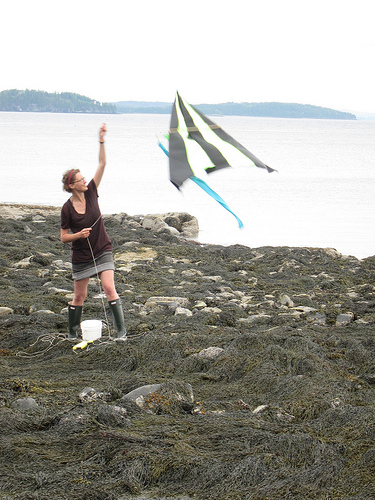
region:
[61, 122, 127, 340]
A woman holding a kite string up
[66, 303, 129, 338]
A pair of black rainboots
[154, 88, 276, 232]
A black, white, and blue kite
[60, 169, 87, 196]
A woman with a pink hairband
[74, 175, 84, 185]
A pair of glasses on her face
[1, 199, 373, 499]
A rocky cliff by the water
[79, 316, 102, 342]
A white bucket on the ground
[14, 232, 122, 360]
White kite string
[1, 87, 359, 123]
Trees and land across the water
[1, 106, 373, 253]
Water between the two areas of land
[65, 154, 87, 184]
girl has brown hair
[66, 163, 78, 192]
girl has pink headband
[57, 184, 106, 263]
girl has brown shirt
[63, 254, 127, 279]
girl has grey skirt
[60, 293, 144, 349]
girl has black boots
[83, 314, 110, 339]
white bucket near girl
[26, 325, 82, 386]
grey rope near bucket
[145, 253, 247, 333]
grey rocks on cliff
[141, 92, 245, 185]
black and white kite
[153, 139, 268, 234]
blue streamer on kite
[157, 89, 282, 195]
a large kite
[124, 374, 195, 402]
a large gray stone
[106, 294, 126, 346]
a woman's black boot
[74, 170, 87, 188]
a woman's eyeglasses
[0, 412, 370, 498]
a section of wet grass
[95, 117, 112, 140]
the hand of a woman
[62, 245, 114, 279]
a woman's short skirt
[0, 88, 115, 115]
a small section of trees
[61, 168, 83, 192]
a woman's brown hair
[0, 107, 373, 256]
a large body of water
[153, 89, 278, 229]
gray and white kite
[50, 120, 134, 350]
woman flying kite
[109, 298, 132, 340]
woman wearing black boot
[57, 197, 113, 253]
red shirt on woman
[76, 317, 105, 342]
white bucket next to woman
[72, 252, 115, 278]
gray skirt on woman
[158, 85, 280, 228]
kite with blue tail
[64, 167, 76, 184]
woman wearing red headband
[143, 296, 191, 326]
large rock on ground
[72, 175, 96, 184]
woman wearing glasses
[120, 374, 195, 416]
Grey rock on the ground.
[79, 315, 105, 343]
White bucket on the ground.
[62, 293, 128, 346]
Black rubber boots on the feet.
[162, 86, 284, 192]
Black and white kite in the sky.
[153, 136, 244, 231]
Blue tail on the kite.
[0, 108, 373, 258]
Water in the background.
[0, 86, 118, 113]
Trees in the background.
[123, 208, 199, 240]
Large grey rocks in the water.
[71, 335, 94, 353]
Yellow kite string handle on the ground.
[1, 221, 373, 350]
Rocky landscape in the background.